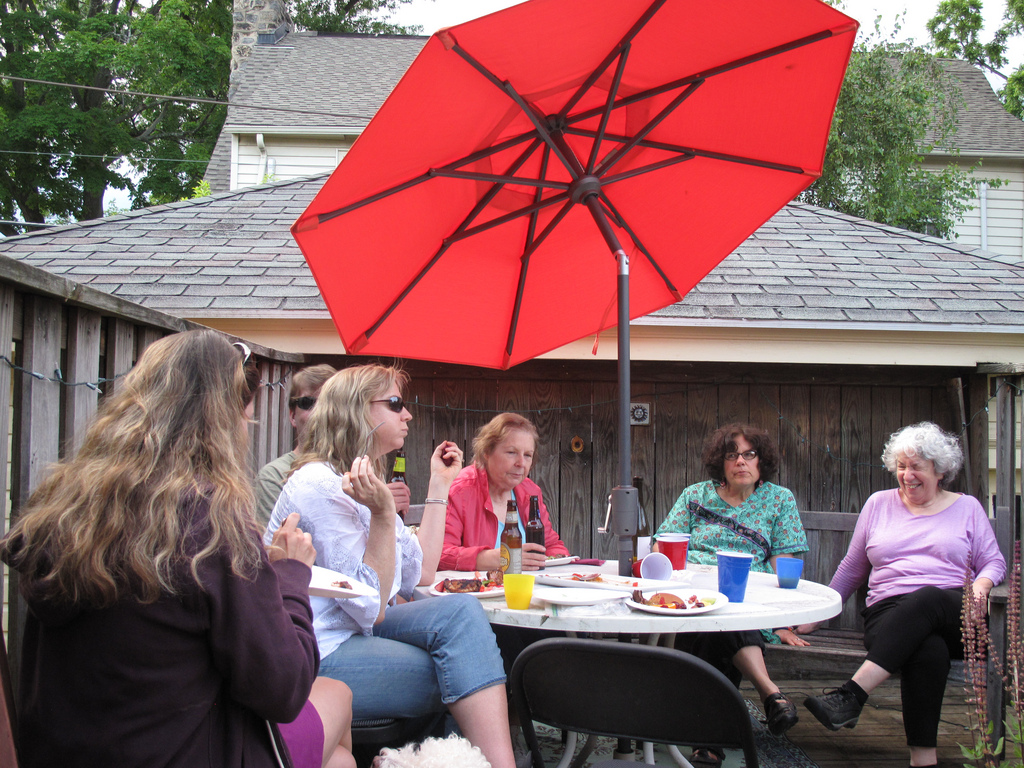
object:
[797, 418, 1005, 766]
lady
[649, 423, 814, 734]
lady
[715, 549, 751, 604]
cup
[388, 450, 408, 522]
bottle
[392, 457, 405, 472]
label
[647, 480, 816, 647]
top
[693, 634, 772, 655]
pants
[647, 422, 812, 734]
woman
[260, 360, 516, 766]
woman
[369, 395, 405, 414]
sunglasses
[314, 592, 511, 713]
pants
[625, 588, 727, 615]
plate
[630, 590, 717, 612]
food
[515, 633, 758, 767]
chair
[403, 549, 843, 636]
table